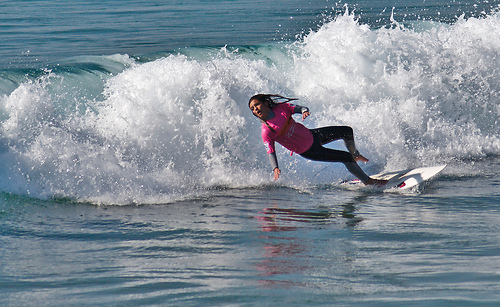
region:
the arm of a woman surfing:
[258, 130, 283, 180]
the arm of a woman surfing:
[280, 102, 314, 122]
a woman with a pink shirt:
[260, 96, 317, 159]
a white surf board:
[323, 164, 450, 196]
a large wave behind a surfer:
[0, 1, 497, 208]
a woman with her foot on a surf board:
[247, 89, 451, 194]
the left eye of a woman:
[255, 101, 260, 106]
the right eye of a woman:
[250, 104, 255, 111]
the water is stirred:
[50, 43, 158, 180]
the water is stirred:
[324, 78, 441, 159]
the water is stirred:
[187, 118, 240, 196]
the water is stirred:
[121, 78, 203, 173]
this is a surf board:
[364, 141, 445, 214]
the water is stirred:
[117, 123, 196, 189]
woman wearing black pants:
[300, 125, 376, 188]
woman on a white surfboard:
[298, 123, 462, 203]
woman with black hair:
[234, 80, 286, 124]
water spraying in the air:
[307, 3, 471, 76]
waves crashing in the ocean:
[57, 74, 249, 176]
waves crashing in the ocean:
[361, 36, 488, 138]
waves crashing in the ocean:
[178, 35, 352, 87]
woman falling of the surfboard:
[245, 83, 457, 220]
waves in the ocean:
[56, 62, 212, 167]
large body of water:
[2, 1, 247, 52]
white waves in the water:
[0, 72, 233, 201]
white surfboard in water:
[329, 164, 452, 201]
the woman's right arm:
[255, 129, 285, 182]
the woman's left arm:
[286, 102, 311, 120]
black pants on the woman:
[306, 118, 377, 183]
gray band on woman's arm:
[264, 151, 278, 171]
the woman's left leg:
[351, 147, 373, 167]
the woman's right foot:
[364, 174, 386, 188]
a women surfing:
[232, 88, 457, 203]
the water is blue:
[164, 215, 285, 297]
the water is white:
[128, 75, 207, 137]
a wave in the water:
[201, 46, 358, 84]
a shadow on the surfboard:
[393, 159, 423, 184]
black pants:
[313, 143, 355, 162]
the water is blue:
[39, 5, 115, 47]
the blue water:
[116, 250, 272, 293]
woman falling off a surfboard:
[245, 90, 445, 189]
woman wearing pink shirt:
[245, 88, 446, 189]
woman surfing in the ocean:
[247, 90, 444, 193]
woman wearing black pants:
[247, 93, 387, 188]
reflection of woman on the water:
[260, 202, 361, 292]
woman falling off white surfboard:
[247, 93, 449, 193]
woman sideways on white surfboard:
[244, 90, 448, 189]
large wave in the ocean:
[1, 5, 498, 205]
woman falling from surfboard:
[245, 87, 447, 192]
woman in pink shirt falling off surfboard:
[243, 91, 449, 191]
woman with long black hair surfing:
[246, 87, 448, 195]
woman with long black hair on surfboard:
[242, 90, 449, 192]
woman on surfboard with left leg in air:
[246, 88, 446, 193]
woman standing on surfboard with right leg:
[235, 85, 452, 202]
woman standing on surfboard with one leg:
[235, 87, 450, 192]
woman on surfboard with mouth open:
[243, 90, 448, 195]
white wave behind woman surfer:
[126, 47, 460, 196]